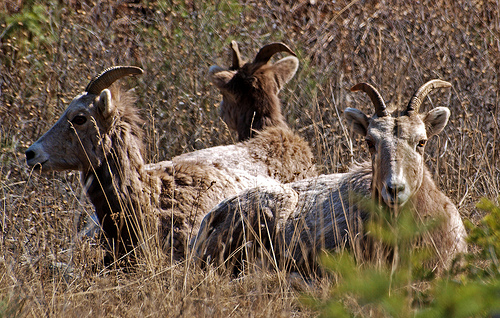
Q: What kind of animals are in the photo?
A: Goats.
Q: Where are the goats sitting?
A: In the grass.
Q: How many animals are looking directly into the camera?
A: 1.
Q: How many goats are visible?
A: 3.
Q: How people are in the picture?
A: None.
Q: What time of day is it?
A: Daytime.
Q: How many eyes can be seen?
A: 3.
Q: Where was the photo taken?
A: On a farmland.